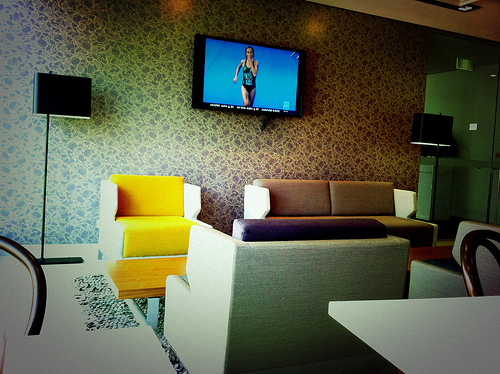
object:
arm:
[97, 178, 119, 219]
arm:
[183, 181, 204, 219]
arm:
[240, 183, 274, 220]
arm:
[390, 188, 421, 216]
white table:
[326, 291, 498, 371]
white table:
[0, 324, 180, 372]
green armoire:
[427, 66, 498, 221]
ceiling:
[317, 2, 499, 39]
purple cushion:
[230, 217, 389, 241]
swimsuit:
[241, 57, 260, 96]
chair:
[407, 220, 499, 298]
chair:
[0, 232, 51, 336]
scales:
[320, 35, 402, 173]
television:
[190, 30, 309, 119]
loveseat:
[240, 178, 437, 245]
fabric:
[269, 180, 396, 216]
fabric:
[124, 175, 186, 251]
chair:
[97, 171, 205, 255]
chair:
[165, 217, 410, 372]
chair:
[457, 229, 499, 296]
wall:
[0, 1, 497, 246]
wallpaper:
[23, 10, 166, 62]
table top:
[97, 256, 194, 298]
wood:
[98, 255, 164, 299]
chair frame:
[95, 172, 125, 261]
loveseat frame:
[240, 184, 269, 219]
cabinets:
[422, 70, 499, 162]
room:
[1, 1, 498, 373]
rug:
[70, 273, 118, 328]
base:
[31, 254, 86, 266]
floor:
[52, 264, 92, 331]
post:
[37, 119, 53, 256]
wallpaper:
[130, 130, 188, 168]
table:
[107, 257, 165, 296]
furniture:
[3, 59, 500, 373]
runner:
[234, 47, 261, 107]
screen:
[190, 32, 308, 119]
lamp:
[408, 109, 458, 240]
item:
[371, 302, 496, 345]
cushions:
[260, 177, 396, 217]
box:
[26, 70, 94, 122]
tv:
[193, 33, 303, 119]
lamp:
[33, 72, 97, 268]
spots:
[123, 79, 137, 91]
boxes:
[414, 158, 456, 222]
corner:
[423, 30, 500, 239]